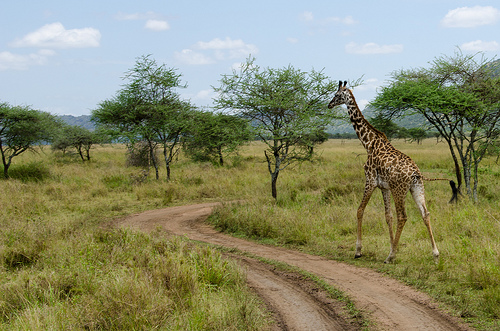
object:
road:
[101, 199, 467, 330]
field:
[0, 137, 499, 329]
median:
[188, 238, 379, 331]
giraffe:
[328, 80, 465, 265]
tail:
[420, 175, 465, 205]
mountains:
[0, 60, 500, 145]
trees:
[0, 100, 64, 178]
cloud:
[9, 21, 101, 50]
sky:
[1, 1, 500, 117]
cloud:
[175, 37, 258, 64]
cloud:
[440, 3, 500, 28]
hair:
[448, 180, 464, 204]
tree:
[210, 53, 365, 200]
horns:
[339, 80, 342, 87]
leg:
[354, 184, 377, 259]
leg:
[381, 190, 394, 249]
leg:
[384, 188, 410, 263]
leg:
[409, 186, 439, 263]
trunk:
[271, 173, 278, 198]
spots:
[375, 146, 393, 173]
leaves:
[250, 76, 321, 110]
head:
[328, 80, 353, 109]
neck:
[346, 98, 380, 146]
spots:
[356, 121, 371, 136]